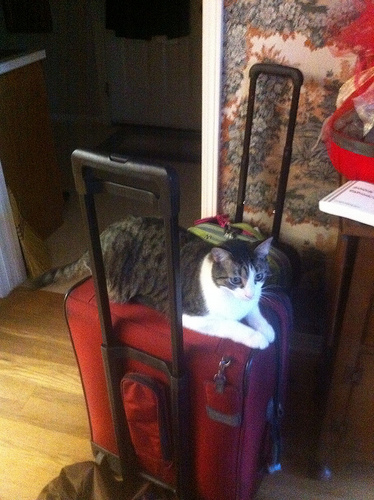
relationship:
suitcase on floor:
[61, 143, 294, 498] [1, 285, 373, 498]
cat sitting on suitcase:
[25, 212, 280, 356] [61, 143, 294, 498]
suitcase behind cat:
[183, 61, 307, 333] [25, 212, 280, 356]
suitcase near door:
[61, 143, 294, 498] [1, 1, 219, 304]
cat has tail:
[25, 212, 280, 356] [29, 248, 93, 291]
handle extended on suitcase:
[67, 142, 201, 497] [61, 143, 294, 498]